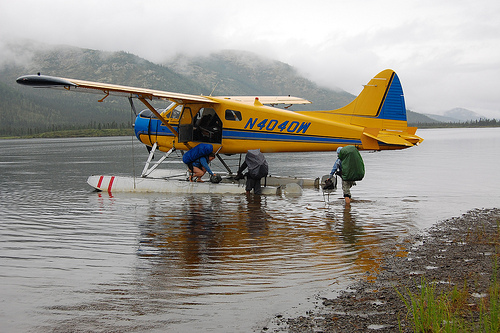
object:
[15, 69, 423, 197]
plane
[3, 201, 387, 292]
ripples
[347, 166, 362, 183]
back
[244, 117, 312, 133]
text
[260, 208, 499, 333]
dirt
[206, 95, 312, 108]
wing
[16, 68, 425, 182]
water plane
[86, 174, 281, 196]
pontoon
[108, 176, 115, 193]
stripe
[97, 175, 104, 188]
stripe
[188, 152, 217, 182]
people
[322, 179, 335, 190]
luggage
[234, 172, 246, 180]
luggage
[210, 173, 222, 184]
luggage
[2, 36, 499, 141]
hills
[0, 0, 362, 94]
fog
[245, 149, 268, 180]
backpack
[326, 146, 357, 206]
guy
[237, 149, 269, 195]
man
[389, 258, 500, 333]
grass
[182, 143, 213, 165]
ruck sack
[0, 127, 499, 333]
lake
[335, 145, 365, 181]
luggage